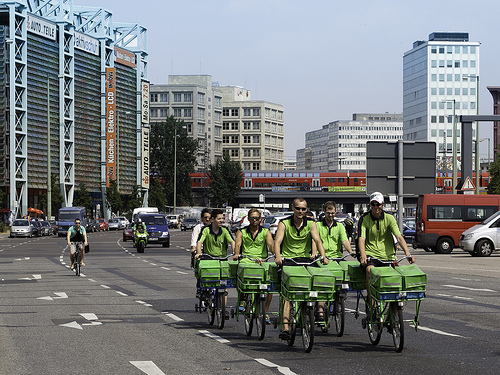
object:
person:
[64, 219, 89, 271]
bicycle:
[67, 241, 85, 277]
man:
[355, 191, 418, 335]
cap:
[369, 191, 384, 204]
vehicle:
[9, 218, 32, 238]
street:
[0, 227, 500, 375]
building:
[218, 83, 286, 170]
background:
[0, 0, 500, 191]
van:
[412, 193, 500, 255]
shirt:
[128, 203, 173, 256]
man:
[132, 218, 149, 239]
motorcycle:
[134, 217, 147, 242]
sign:
[142, 127, 150, 189]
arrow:
[58, 312, 103, 330]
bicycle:
[361, 254, 427, 353]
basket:
[280, 265, 336, 302]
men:
[194, 208, 236, 320]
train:
[150, 169, 366, 191]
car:
[133, 214, 170, 248]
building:
[1, 1, 151, 226]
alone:
[64, 218, 90, 276]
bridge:
[190, 186, 368, 205]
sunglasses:
[293, 206, 307, 211]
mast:
[219, 85, 251, 103]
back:
[365, 140, 437, 199]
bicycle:
[272, 255, 337, 353]